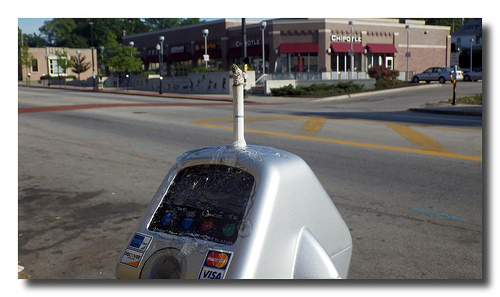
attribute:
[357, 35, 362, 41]
letter — e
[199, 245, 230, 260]
logo — mastercard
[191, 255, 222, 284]
logo — visa